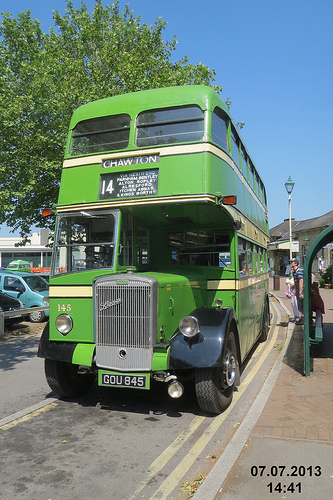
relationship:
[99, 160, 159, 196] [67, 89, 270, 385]
marquee of bus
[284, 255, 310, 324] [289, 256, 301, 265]
man wearing baseball cap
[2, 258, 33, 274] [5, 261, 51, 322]
van in parking lot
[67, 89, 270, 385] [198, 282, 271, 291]
bus with stripes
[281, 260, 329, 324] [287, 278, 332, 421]
people on sidewalk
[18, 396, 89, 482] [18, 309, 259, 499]
stains on street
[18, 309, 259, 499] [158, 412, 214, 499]
street with lines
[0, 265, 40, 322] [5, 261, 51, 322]
cars in parking lot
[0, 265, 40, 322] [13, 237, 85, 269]
cars in front of building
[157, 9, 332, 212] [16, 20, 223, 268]
sky over trees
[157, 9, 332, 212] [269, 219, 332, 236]
sky over roofs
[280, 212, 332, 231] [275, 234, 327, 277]
roof over building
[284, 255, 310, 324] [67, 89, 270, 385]
man leaning toward bus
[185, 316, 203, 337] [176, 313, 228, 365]
headlight over wheel cover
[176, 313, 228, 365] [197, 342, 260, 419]
wheel cover over tire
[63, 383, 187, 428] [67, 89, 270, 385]
shadow below bus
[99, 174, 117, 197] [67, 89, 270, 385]
number 14 on bus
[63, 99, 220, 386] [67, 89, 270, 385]
front of bus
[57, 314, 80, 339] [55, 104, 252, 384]
light of double decker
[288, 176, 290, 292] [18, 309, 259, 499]
light post on street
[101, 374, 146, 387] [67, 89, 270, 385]
license plate of bus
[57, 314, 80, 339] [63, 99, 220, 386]
light on front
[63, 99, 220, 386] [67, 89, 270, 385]
front on bus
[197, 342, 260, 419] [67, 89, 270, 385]
tire of bus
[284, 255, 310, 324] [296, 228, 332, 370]
man standing at bus stop